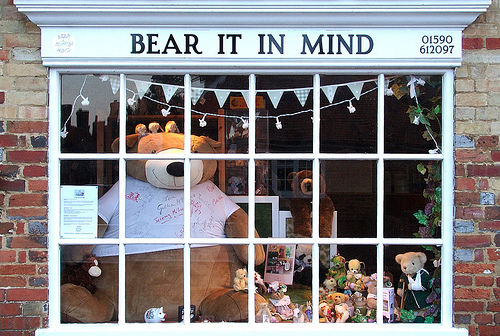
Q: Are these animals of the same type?
A: Yes, all the animals are bears.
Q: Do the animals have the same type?
A: Yes, all the animals are bears.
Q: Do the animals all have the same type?
A: Yes, all the animals are bears.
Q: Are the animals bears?
A: Yes, all the animals are bears.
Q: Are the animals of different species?
A: No, all the animals are bears.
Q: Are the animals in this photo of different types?
A: No, all the animals are bears.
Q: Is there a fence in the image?
A: No, there are no fences.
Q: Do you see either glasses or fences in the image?
A: No, there are no fences or glasses.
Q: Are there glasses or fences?
A: No, there are no fences or glasses.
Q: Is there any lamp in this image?
A: No, there are no lamps.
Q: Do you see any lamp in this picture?
A: No, there are no lamps.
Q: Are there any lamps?
A: No, there are no lamps.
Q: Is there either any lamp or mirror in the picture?
A: No, there are no lamps or mirrors.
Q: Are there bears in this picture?
A: Yes, there is a bear.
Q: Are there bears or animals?
A: Yes, there is a bear.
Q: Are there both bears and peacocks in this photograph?
A: No, there is a bear but no peacocks.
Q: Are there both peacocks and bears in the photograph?
A: No, there is a bear but no peacocks.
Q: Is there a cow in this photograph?
A: No, there are no cows.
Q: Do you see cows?
A: No, there are no cows.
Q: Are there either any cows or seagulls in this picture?
A: No, there are no cows or seagulls.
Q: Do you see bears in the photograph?
A: Yes, there is a bear.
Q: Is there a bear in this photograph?
A: Yes, there is a bear.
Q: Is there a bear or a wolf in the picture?
A: Yes, there is a bear.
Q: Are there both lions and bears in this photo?
A: No, there is a bear but no lions.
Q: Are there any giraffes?
A: No, there are no giraffes.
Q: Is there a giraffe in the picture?
A: No, there are no giraffes.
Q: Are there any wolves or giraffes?
A: No, there are no giraffes or wolves.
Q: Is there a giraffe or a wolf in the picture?
A: No, there are no giraffes or wolves.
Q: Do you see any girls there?
A: No, there are no girls.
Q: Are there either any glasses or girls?
A: No, there are no girls or glasses.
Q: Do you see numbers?
A: Yes, there are numbers.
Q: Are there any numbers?
A: Yes, there are numbers.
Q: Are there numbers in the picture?
A: Yes, there are numbers.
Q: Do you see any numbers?
A: Yes, there are numbers.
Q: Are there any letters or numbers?
A: Yes, there are numbers.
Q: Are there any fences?
A: No, there are no fences.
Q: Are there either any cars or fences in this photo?
A: No, there are no fences or cars.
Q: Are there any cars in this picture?
A: No, there are no cars.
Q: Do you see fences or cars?
A: No, there are no cars or fences.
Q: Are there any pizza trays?
A: No, there are no pizza trays.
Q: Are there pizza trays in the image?
A: No, there are no pizza trays.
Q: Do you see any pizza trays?
A: No, there are no pizza trays.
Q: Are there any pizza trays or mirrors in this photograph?
A: No, there are no pizza trays or mirrors.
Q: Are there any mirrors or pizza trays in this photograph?
A: No, there are no pizza trays or mirrors.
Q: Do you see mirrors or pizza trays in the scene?
A: No, there are no pizza trays or mirrors.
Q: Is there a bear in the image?
A: Yes, there is a bear.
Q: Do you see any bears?
A: Yes, there is a bear.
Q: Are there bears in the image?
A: Yes, there is a bear.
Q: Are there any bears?
A: Yes, there is a bear.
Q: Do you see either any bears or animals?
A: Yes, there is a bear.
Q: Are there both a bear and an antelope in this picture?
A: No, there is a bear but no antelopes.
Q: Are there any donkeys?
A: No, there are no donkeys.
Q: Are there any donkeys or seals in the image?
A: No, there are no donkeys or seals.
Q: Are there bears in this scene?
A: Yes, there is a bear.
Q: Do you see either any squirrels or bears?
A: Yes, there is a bear.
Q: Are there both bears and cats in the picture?
A: No, there is a bear but no cats.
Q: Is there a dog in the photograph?
A: No, there are no dogs.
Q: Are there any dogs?
A: No, there are no dogs.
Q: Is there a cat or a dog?
A: No, there are no dogs or cats.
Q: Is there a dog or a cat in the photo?
A: No, there are no dogs or cats.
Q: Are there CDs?
A: No, there are no cds.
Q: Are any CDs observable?
A: No, there are no cds.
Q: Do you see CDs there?
A: No, there are no cds.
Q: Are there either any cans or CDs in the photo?
A: No, there are no CDs or cans.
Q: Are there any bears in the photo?
A: Yes, there is a bear.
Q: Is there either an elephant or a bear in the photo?
A: Yes, there is a bear.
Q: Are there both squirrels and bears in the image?
A: No, there is a bear but no squirrels.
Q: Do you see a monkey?
A: No, there are no monkeys.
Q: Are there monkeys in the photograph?
A: No, there are no monkeys.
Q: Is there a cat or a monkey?
A: No, there are no monkeys or cats.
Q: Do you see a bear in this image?
A: Yes, there is a bear.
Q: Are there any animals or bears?
A: Yes, there is a bear.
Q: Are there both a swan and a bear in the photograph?
A: No, there is a bear but no swans.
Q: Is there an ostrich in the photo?
A: No, there are no ostriches.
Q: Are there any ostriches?
A: No, there are no ostriches.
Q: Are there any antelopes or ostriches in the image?
A: No, there are no ostriches or antelopes.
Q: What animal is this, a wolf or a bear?
A: This is a bear.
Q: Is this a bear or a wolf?
A: This is a bear.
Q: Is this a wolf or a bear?
A: This is a bear.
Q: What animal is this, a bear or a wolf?
A: This is a bear.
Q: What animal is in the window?
A: The bear is in the window.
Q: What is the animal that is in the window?
A: The animal is a bear.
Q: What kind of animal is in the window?
A: The animal is a bear.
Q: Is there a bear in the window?
A: Yes, there is a bear in the window.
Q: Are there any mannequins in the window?
A: No, there is a bear in the window.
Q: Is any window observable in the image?
A: Yes, there is a window.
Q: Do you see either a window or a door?
A: Yes, there is a window.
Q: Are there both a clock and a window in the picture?
A: No, there is a window but no clocks.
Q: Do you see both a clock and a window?
A: No, there is a window but no clocks.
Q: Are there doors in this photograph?
A: No, there are no doors.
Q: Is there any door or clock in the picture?
A: No, there are no doors or clocks.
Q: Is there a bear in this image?
A: Yes, there is a bear.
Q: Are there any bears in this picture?
A: Yes, there is a bear.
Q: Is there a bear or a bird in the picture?
A: Yes, there is a bear.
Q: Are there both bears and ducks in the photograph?
A: No, there is a bear but no ducks.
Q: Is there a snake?
A: No, there are no snakes.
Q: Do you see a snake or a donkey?
A: No, there are no snakes or donkeys.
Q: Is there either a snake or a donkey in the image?
A: No, there are no snakes or donkeys.